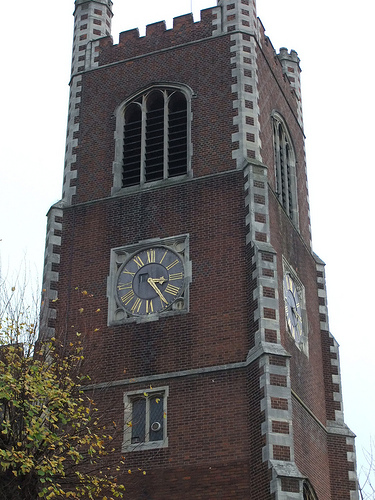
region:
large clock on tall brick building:
[113, 244, 185, 313]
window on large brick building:
[121, 385, 169, 452]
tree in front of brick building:
[0, 255, 165, 498]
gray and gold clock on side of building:
[282, 264, 306, 350]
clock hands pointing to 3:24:
[146, 277, 170, 306]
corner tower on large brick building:
[275, 47, 303, 98]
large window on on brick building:
[271, 112, 298, 225]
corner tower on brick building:
[69, 0, 112, 73]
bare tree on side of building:
[357, 436, 374, 498]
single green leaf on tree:
[61, 418, 67, 424]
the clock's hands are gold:
[102, 254, 185, 313]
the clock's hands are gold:
[93, 220, 228, 359]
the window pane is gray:
[116, 383, 193, 466]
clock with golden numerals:
[114, 244, 186, 315]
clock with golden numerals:
[281, 259, 309, 357]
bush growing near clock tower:
[1, 249, 145, 498]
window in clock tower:
[118, 387, 169, 450]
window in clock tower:
[301, 477, 321, 498]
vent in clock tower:
[109, 82, 194, 196]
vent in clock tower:
[270, 111, 302, 231]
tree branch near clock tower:
[359, 435, 373, 499]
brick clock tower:
[38, 0, 360, 498]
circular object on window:
[150, 422, 160, 430]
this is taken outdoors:
[32, 15, 274, 488]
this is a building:
[42, 54, 238, 344]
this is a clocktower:
[44, 232, 317, 402]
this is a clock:
[94, 235, 238, 331]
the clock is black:
[94, 227, 246, 355]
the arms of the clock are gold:
[106, 245, 191, 312]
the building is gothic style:
[55, 293, 284, 444]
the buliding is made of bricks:
[100, 332, 304, 398]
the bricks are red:
[99, 326, 289, 398]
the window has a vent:
[101, 91, 200, 181]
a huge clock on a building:
[98, 230, 199, 329]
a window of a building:
[117, 384, 177, 454]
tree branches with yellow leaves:
[0, 274, 137, 499]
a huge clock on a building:
[273, 249, 319, 362]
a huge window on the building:
[103, 74, 204, 199]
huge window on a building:
[264, 102, 308, 238]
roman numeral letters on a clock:
[144, 250, 160, 265]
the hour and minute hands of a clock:
[140, 268, 174, 307]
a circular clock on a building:
[105, 227, 198, 326]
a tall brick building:
[49, 3, 364, 498]